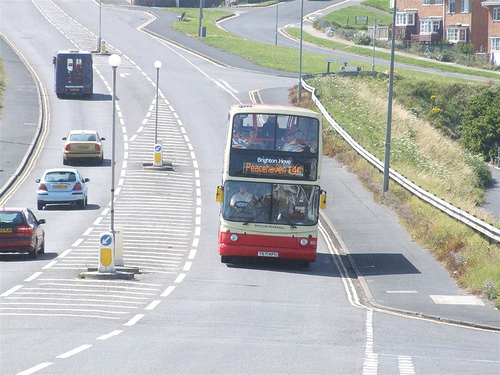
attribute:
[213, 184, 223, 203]
mirror — passenger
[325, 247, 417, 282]
shadow — bus 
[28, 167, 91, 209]
car — white, motion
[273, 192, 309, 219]
window — lower front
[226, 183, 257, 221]
window — lower  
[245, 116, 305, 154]
window — upper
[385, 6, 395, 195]
pole — tall, metal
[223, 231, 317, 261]
bumper — red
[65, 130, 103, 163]
car — white, running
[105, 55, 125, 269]
pole — tall, metal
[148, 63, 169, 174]
pole — tall, metal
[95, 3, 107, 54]
pole — tall, metal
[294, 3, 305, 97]
pole — tall, metal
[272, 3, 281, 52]
pole — tall, metal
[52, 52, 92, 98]
truck — running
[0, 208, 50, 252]
car — red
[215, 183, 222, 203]
mirror — yellow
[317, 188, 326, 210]
mirror — yellow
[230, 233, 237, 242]
light — off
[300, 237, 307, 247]
light — off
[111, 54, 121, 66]
light — white, round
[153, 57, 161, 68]
light — white, round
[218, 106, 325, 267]
bus — running, double-decker, red, white, moving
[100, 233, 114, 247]
arrow — white